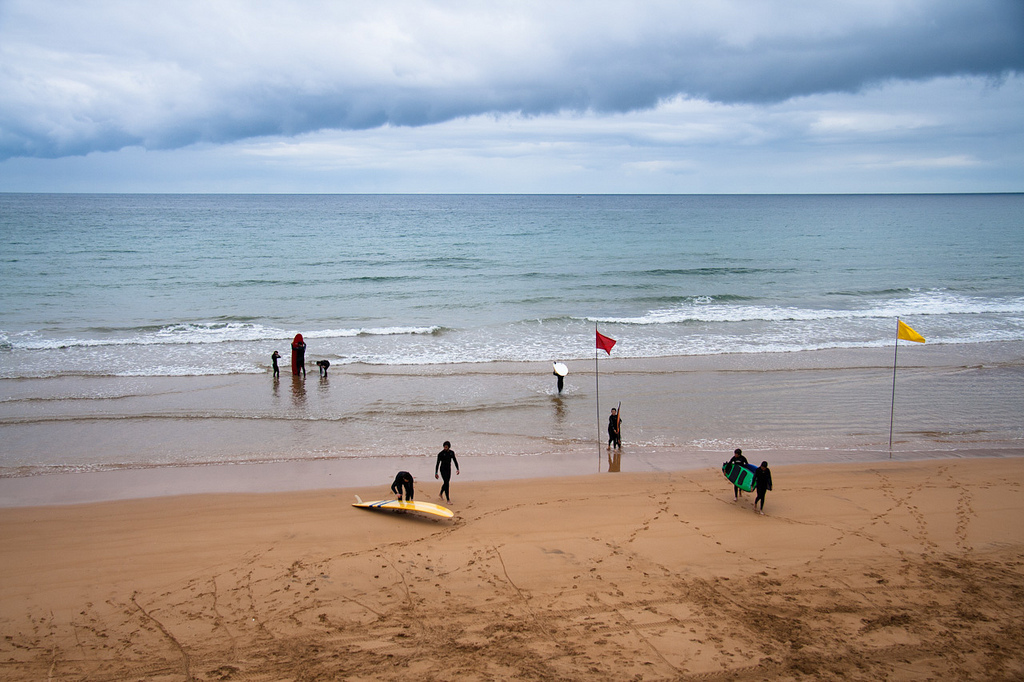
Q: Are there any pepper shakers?
A: No, there are no pepper shakers.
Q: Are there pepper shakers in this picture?
A: No, there are no pepper shakers.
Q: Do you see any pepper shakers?
A: No, there are no pepper shakers.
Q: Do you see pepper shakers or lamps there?
A: No, there are no pepper shakers or lamps.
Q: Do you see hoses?
A: No, there are no hoses.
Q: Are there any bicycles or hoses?
A: No, there are no hoses or bicycles.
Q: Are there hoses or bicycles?
A: No, there are no hoses or bicycles.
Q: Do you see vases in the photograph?
A: No, there are no vases.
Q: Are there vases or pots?
A: No, there are no vases or pots.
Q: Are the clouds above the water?
A: Yes, the clouds are above the water.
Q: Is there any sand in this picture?
A: Yes, there is sand.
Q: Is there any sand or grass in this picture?
A: Yes, there is sand.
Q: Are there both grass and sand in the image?
A: No, there is sand but no grass.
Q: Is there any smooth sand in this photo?
A: Yes, there is smooth sand.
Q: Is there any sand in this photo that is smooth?
A: Yes, there is sand that is smooth.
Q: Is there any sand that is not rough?
A: Yes, there is smooth sand.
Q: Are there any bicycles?
A: No, there are no bicycles.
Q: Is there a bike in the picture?
A: No, there are no bikes.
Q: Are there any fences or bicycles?
A: No, there are no bicycles or fences.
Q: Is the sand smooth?
A: Yes, the sand is smooth.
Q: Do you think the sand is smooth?
A: Yes, the sand is smooth.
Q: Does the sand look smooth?
A: Yes, the sand is smooth.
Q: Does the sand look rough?
A: No, the sand is smooth.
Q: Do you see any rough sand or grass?
A: No, there is sand but it is smooth.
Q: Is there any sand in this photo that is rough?
A: No, there is sand but it is smooth.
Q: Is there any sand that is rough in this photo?
A: No, there is sand but it is smooth.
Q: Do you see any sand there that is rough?
A: No, there is sand but it is smooth.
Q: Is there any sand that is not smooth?
A: No, there is sand but it is smooth.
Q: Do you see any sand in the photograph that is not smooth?
A: No, there is sand but it is smooth.